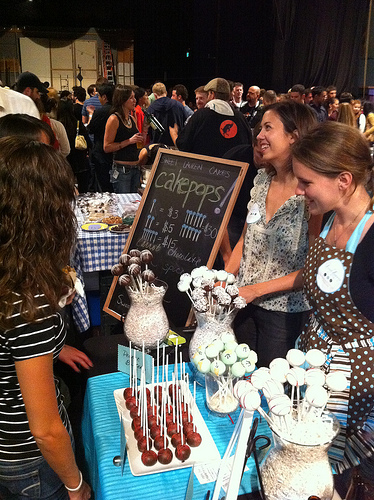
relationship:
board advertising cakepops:
[103, 147, 249, 344] [149, 168, 226, 214]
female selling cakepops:
[218, 98, 326, 370] [122, 333, 201, 469]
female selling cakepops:
[225, 118, 361, 492] [122, 333, 201, 469]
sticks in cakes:
[124, 335, 200, 445] [123, 382, 205, 469]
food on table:
[77, 193, 136, 233] [66, 190, 151, 285]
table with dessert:
[78, 354, 292, 498] [121, 337, 204, 468]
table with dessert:
[78, 354, 292, 498] [193, 335, 257, 421]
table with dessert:
[78, 354, 292, 498] [232, 345, 349, 498]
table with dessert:
[78, 354, 292, 498] [178, 263, 249, 386]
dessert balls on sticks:
[121, 385, 200, 468] [123, 338, 197, 452]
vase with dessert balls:
[259, 404, 343, 497] [226, 346, 350, 414]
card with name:
[115, 342, 154, 386] [119, 350, 142, 370]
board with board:
[103, 147, 249, 344] [103, 147, 249, 344]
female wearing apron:
[289, 115, 374, 500] [296, 216, 362, 465]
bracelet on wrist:
[64, 472, 85, 489] [49, 466, 94, 496]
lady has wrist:
[0, 139, 92, 500] [49, 466, 94, 496]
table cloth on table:
[78, 379, 108, 499] [80, 362, 265, 498]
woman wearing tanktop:
[107, 82, 149, 184] [112, 117, 138, 159]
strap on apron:
[317, 216, 334, 240] [285, 208, 362, 476]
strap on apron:
[338, 213, 362, 259] [285, 208, 362, 476]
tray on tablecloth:
[113, 378, 223, 475] [79, 354, 280, 496]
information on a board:
[139, 176, 229, 255] [103, 120, 251, 345]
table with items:
[68, 172, 153, 272] [64, 172, 127, 255]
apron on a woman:
[289, 235, 372, 460] [252, 110, 372, 450]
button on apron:
[308, 247, 348, 307] [284, 238, 372, 431]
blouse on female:
[224, 187, 305, 316] [218, 98, 325, 370]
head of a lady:
[2, 130, 65, 289] [0, 139, 92, 500]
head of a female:
[265, 125, 372, 471] [289, 115, 374, 500]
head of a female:
[238, 75, 317, 177] [218, 98, 325, 370]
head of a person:
[173, 72, 250, 164] [188, 73, 236, 106]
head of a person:
[148, 74, 171, 103] [136, 66, 189, 157]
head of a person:
[3, 60, 49, 115] [3, 57, 43, 105]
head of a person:
[301, 78, 335, 105] [298, 72, 336, 128]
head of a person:
[280, 68, 320, 120] [281, 78, 312, 107]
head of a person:
[255, 80, 281, 108] [251, 82, 291, 105]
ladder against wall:
[92, 43, 126, 87] [40, 47, 121, 79]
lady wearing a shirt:
[0, 288, 84, 497] [1, 146, 98, 498]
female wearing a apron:
[289, 115, 374, 500] [281, 216, 370, 449]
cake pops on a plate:
[114, 338, 211, 476] [82, 336, 224, 478]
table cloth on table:
[78, 342, 247, 498] [82, 356, 253, 494]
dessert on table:
[178, 263, 249, 386] [66, 350, 244, 498]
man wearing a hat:
[182, 61, 254, 148] [190, 65, 238, 105]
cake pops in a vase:
[171, 258, 240, 320] [171, 259, 253, 365]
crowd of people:
[8, 25, 359, 431] [10, 55, 373, 460]